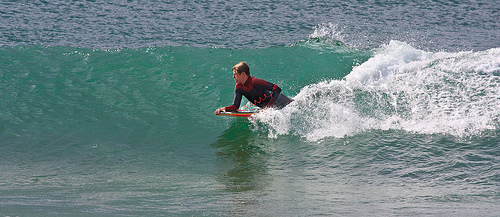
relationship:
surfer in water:
[215, 62, 294, 117] [1, 1, 499, 216]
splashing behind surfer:
[286, 39, 499, 140] [215, 62, 294, 117]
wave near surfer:
[2, 44, 379, 130] [215, 62, 294, 117]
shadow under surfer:
[215, 117, 267, 202] [215, 62, 294, 117]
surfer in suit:
[215, 62, 294, 117] [224, 77, 294, 110]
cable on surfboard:
[242, 91, 274, 111] [217, 108, 267, 116]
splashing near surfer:
[286, 39, 499, 140] [215, 62, 294, 117]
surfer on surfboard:
[215, 62, 294, 117] [217, 108, 267, 116]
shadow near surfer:
[215, 117, 267, 202] [215, 62, 294, 117]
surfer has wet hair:
[215, 62, 294, 117] [233, 62, 251, 77]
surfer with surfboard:
[215, 62, 294, 117] [217, 108, 267, 116]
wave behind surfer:
[2, 44, 379, 130] [215, 62, 294, 117]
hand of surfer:
[215, 106, 228, 116] [215, 62, 294, 117]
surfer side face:
[215, 62, 294, 117] [233, 71, 248, 82]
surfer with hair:
[215, 62, 294, 117] [233, 62, 251, 77]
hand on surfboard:
[215, 106, 228, 116] [217, 108, 267, 116]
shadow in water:
[215, 117, 267, 202] [1, 1, 499, 216]